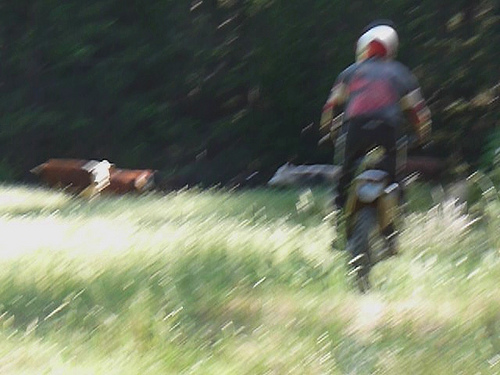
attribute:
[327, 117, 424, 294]
bike — in air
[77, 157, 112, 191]
head — white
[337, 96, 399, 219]
jeans — dark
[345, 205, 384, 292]
tire — slanted, black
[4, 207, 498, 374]
grass — tan, green, shining, slanting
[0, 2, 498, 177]
trees — dark green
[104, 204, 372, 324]
grasses — tall, green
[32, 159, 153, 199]
object — brown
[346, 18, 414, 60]
helmet — white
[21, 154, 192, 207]
cows — brown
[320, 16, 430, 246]
person — riding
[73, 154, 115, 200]
object — curved, tan, reflecting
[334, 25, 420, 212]
person — wearing black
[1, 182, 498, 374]
grass — tall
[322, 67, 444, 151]
shirt — black, red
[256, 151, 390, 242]
animal — gray, black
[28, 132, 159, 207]
object — rectangular, brown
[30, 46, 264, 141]
wall — dark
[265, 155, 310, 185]
head — slanted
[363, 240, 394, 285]
prongs — silver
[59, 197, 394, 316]
field — grassy